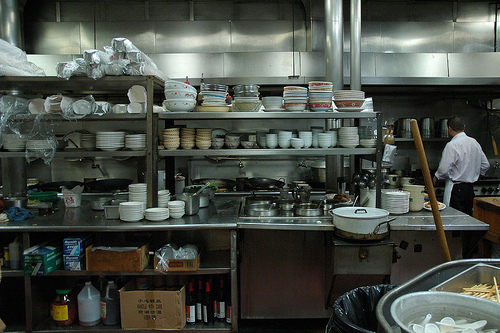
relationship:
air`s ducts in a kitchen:
[21, 0, 497, 78] [3, 4, 493, 331]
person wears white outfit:
[431, 114, 492, 216] [437, 133, 492, 180]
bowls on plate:
[333, 87, 363, 107] [335, 105, 365, 112]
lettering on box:
[135, 297, 165, 320] [118, 277, 190, 329]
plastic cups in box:
[115, 213, 227, 307] [156, 255, 202, 270]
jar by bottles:
[49, 283, 77, 328] [73, 277, 102, 327]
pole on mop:
[409, 118, 452, 262] [407, 105, 457, 264]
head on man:
[445, 112, 467, 135] [430, 113, 491, 216]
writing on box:
[137, 299, 164, 324] [119, 289, 185, 330]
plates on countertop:
[378, 187, 414, 217] [1, 193, 493, 235]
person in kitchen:
[431, 114, 491, 253] [3, 4, 493, 331]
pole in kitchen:
[412, 117, 454, 262] [3, 4, 493, 331]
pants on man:
[448, 182, 475, 217] [430, 113, 491, 216]